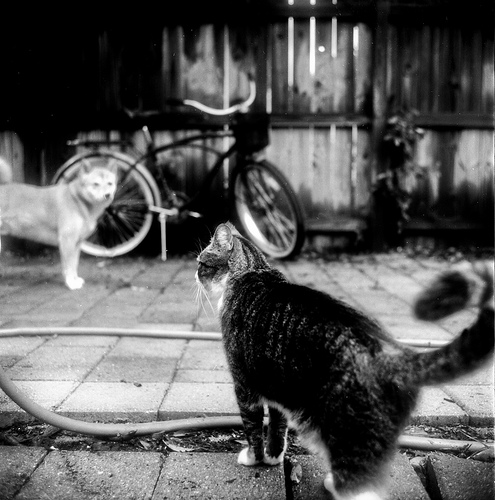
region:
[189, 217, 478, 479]
cat looking away from camera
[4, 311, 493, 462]
Hose on the patio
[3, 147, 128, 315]
Dog looking towards cat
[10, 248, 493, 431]
Paver patio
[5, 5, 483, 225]
Wood fence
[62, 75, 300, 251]
Old style bike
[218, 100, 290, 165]
Basket on the bikes handle bars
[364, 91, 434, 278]
Plant against the fence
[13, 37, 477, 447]
Photo in black and white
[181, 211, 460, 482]
Cat is the only thing in focus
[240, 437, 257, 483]
Cat has white paw.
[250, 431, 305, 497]
Cat has white paw.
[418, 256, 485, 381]
Cat has dark tail.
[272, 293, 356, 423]
Cat has dark fur on back.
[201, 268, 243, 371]
Cat has white chin.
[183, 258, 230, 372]
Cat has white whiskers.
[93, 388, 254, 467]
Hose on ground in front of cat.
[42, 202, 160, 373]
Dog standing across from cat.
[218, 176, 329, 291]
Bike behind dog in distance.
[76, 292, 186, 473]
Ground is made of bricks.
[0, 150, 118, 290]
The white dog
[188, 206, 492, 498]
The grey and white cat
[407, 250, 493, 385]
The tail of the cat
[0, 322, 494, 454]
The hose in front of the cat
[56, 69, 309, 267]
The bike behind the dog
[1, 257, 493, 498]
The walkway made of bricks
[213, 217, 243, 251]
The ears of the cat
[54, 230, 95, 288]
The dog's front legs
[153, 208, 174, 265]
The bikes kickstand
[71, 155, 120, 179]
The ears of the dog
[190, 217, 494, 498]
A cat on the sidewalk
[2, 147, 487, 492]
A cat sees a dog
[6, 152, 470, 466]
A dog sees a cat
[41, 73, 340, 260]
A cruiser bike against a fence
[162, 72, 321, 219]
A bike with a basket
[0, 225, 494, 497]
A hose to trip over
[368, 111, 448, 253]
A sapling trying to grow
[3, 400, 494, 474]
leaves in a hole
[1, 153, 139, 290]
An alert dog perhaps a huskie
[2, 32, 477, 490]
Pets patrolling the neighborhood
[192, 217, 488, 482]
a cat standing on the patio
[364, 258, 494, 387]
the cat's tail is curled on the tip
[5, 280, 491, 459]
hoses are crossing the patio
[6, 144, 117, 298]
a dog is on the patio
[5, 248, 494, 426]
the patio is made of cement tiles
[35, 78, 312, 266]
a bike is parked on the patio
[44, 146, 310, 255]
the bike has fenders on the tires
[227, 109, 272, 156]
a small basket is on the front of the bike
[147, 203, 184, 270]
the bike has a kick stand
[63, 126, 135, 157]
the bike has a rack on the back fender